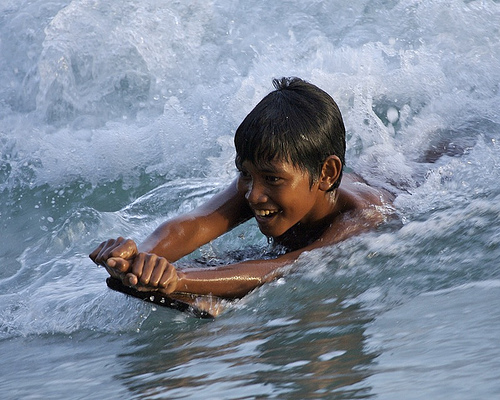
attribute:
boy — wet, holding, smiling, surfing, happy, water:
[129, 89, 384, 302]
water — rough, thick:
[66, 28, 181, 57]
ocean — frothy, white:
[357, 3, 474, 58]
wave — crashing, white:
[267, 337, 441, 362]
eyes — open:
[227, 164, 289, 191]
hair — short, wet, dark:
[240, 94, 340, 157]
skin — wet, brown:
[331, 179, 366, 232]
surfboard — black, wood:
[116, 292, 198, 316]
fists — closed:
[73, 228, 173, 285]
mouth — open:
[249, 209, 285, 220]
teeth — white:
[252, 210, 267, 220]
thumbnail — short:
[128, 274, 139, 284]